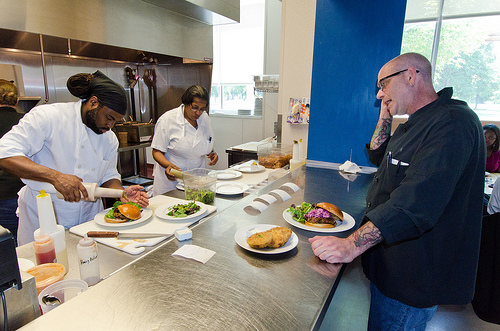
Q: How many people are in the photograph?
A: Three.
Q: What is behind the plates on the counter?
A: Receipts.